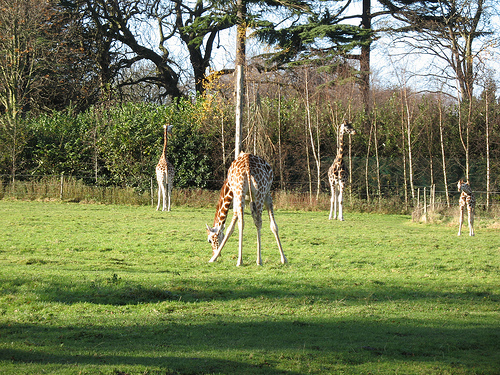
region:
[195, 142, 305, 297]
brown and beige giraffe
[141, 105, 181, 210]
brown and beige giraffe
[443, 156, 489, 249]
small brown giraffe in grass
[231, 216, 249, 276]
leg of a giraffe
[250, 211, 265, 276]
leg of a giraffe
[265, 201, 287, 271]
leg of a giraffe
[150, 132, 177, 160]
long neck of a giraffe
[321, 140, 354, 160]
long neck of a giraffe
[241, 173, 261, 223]
tail of a giraffe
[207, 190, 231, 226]
long neck of a giraffe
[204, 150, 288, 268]
Giraffe grazing on field of grass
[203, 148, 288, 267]
Giraffe in front of large white pole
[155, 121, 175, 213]
Giraffe in a grass field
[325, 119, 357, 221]
Giraffe in a grass field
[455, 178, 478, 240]
Baby giraffe on a grass field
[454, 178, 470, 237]
Baby giraffe next to three larger giraffes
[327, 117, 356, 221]
Large giraffe next to a baby giraffe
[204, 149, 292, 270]
Giraffe grazing between two other giraffes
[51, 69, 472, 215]
Trees behind a group of giraffes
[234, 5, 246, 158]
Large white pole behind a group of giraffes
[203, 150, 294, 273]
giraffe bending down to eat grass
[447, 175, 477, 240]
a young giraffe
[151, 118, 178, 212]
giraffe standing straight up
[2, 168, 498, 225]
a fence behind the giraffes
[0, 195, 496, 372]
flat land covered in green grass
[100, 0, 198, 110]
a twisted tree branch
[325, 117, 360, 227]
giraffe facing to the right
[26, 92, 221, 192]
tall hedges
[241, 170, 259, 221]
a giraffe tail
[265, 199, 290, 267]
front right giraffe leg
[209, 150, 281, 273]
a giraffe in the middle is bent over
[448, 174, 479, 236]
a baby giraffe walks beside the fence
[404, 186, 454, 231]
fence posts mark the edge of the field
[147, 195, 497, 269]
four giraffes are on a grassy field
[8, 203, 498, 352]
the grass is green and thick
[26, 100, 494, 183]
tall shrubs line the edge of the field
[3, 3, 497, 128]
leaves on the tall trees have turned yellow or fallen off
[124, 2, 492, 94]
blue skies are seen through the trees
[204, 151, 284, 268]
one giraffe grazes on the grass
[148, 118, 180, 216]
the giraffe at the edge of the field is staring at the trees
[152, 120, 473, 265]
four giraffes standing in a fenced area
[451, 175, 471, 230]
a baby African giraffe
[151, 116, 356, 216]
two long neck giraffes standing erect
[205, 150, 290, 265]
a giraffe eating grass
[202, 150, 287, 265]
a brown spotted giraffe eating green grass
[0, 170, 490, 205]
a barb wire fence on wood poles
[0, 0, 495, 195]
tall trees behind the giraffe's habitat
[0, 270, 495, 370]
green grass on the ground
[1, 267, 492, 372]
green grass for the giraffes to eat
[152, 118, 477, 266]
four African descent giraffes in a national park